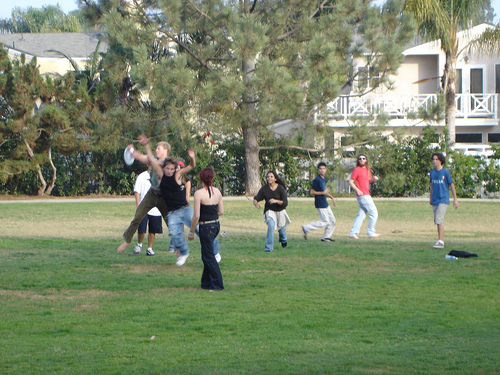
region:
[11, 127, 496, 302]
a group is playing frisbee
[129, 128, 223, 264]
a boy is jumping for the frisbee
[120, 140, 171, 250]
the boy caught the frisbee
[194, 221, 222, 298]
the girl is wearing dark jeans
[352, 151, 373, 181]
the boy is wearing sunglasses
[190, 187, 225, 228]
the girl has a tube top on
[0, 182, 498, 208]
the park has a walkway around it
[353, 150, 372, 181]
the man has long hair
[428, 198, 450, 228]
the boy is wearing khaki shorts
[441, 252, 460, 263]
a plastic bottle is on the ground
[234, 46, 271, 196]
a tall gray tree branch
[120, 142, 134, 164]
a large white Frisbee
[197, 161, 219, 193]
a woman's red hair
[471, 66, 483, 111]
the door of a home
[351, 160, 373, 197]
a man's short sleeve red shirt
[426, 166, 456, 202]
a man's short sleeve blue shirt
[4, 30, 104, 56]
part of a rooftop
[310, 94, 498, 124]
a long white balcony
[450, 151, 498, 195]
green tree leaves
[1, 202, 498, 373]
a large green field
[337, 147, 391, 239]
man wearing red shirt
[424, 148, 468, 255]
man wearing blue shirt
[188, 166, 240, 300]
woman in all black outfit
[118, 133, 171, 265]
man catching a frisbee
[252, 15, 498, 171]
large house in the background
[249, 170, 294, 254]
woman wearing long sleeve black shirt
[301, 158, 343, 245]
man running on the grass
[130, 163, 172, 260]
man wearing white shirt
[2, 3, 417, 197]
line of trees in the distance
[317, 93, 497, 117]
white railing of the house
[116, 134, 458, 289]
a group of people playing Frisbee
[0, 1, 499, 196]
trees behind the group of people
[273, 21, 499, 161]
a white house behind the group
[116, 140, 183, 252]
a young man catching the Frisbee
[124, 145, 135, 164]
a white Frisbee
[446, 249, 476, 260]
possessions resting on the ground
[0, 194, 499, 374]
a grassy field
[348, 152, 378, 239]
a man with sunglasses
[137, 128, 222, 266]
a man failing to grab the Frisbee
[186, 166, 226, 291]
a woman passively participating in the game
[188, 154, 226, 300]
girl getting chased by kid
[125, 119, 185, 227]
kids playing frisbee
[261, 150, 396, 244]
three guys running for frisbee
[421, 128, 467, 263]
kid in blue shirt waiting for frisbee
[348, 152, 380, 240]
red shirted kid waiting for frisbee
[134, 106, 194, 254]
boy in black tanktop chasing girl;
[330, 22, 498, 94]
two story white house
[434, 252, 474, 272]
bottle of water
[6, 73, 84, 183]
pine tree in background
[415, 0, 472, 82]
tall palm tree